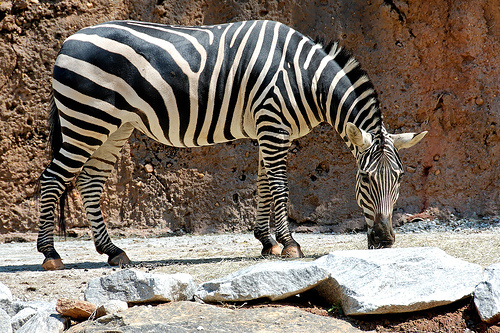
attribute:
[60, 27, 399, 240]
zebra — pictured, striped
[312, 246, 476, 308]
rocks — large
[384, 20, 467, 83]
wall — red, enclosure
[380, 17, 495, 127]
stone — red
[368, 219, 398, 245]
nose — black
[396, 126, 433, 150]
ear — white, zebra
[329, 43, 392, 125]
mane — stripped, zebras, black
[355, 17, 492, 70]
rock — red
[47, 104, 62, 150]
tail — black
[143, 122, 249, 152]
belly — round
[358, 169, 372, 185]
eye — black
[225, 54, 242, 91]
spot — white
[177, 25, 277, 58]
stripes — black